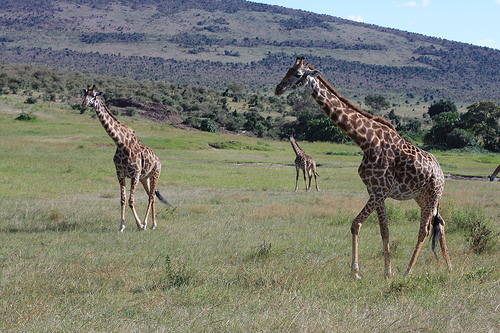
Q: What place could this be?
A: It is a plain.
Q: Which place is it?
A: It is a plain.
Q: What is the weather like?
A: It is clear.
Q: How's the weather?
A: It is clear.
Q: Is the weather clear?
A: Yes, it is clear.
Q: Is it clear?
A: Yes, it is clear.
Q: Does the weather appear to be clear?
A: Yes, it is clear.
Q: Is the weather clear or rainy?
A: It is clear.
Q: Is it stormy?
A: No, it is clear.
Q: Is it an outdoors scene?
A: Yes, it is outdoors.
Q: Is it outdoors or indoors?
A: It is outdoors.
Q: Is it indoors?
A: No, it is outdoors.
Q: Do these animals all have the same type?
A: Yes, all the animals are giraffes.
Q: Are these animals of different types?
A: No, all the animals are giraffes.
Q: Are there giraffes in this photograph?
A: Yes, there is a giraffe.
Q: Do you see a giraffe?
A: Yes, there is a giraffe.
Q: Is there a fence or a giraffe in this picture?
A: Yes, there is a giraffe.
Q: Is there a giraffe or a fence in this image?
A: Yes, there is a giraffe.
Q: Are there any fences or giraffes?
A: Yes, there is a giraffe.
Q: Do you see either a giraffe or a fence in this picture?
A: Yes, there is a giraffe.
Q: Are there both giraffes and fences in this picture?
A: No, there is a giraffe but no fences.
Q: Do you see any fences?
A: No, there are no fences.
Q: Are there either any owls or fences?
A: No, there are no fences or owls.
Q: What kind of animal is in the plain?
A: The animal is a giraffe.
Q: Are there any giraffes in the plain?
A: Yes, there is a giraffe in the plain.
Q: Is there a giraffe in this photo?
A: Yes, there is a giraffe.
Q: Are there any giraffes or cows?
A: Yes, there is a giraffe.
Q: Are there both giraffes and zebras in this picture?
A: No, there is a giraffe but no zebras.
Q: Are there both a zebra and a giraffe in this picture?
A: No, there is a giraffe but no zebras.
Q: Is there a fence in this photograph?
A: No, there are no fences.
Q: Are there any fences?
A: No, there are no fences.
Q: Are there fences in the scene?
A: No, there are no fences.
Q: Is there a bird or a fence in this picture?
A: No, there are no fences or birds.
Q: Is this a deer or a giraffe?
A: This is a giraffe.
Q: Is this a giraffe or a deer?
A: This is a giraffe.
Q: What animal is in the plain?
A: The giraffe is in the plain.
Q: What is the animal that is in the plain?
A: The animal is a giraffe.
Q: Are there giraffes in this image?
A: Yes, there is a giraffe.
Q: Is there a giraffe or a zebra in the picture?
A: Yes, there is a giraffe.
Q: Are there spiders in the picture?
A: No, there are no spiders.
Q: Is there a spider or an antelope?
A: No, there are no spiders or antelopes.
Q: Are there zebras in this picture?
A: No, there are no zebras.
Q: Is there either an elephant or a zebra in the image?
A: No, there are no zebras or elephants.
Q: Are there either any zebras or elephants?
A: No, there are no zebras or elephants.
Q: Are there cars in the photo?
A: No, there are no cars.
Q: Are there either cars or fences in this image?
A: No, there are no cars or fences.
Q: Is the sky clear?
A: Yes, the sky is clear.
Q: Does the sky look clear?
A: Yes, the sky is clear.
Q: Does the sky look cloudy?
A: No, the sky is clear.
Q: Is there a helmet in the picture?
A: No, there are no helmets.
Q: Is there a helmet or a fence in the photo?
A: No, there are no helmets or fences.